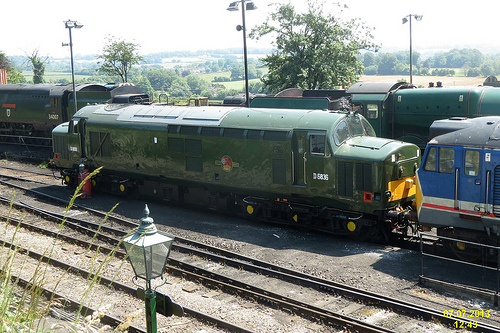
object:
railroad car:
[49, 98, 409, 236]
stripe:
[383, 174, 416, 203]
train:
[413, 95, 500, 259]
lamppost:
[139, 285, 164, 333]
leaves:
[319, 59, 336, 63]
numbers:
[319, 173, 323, 181]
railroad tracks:
[7, 261, 188, 332]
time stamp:
[434, 305, 499, 332]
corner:
[431, 289, 499, 331]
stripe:
[421, 196, 498, 226]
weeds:
[68, 219, 125, 328]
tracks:
[242, 255, 500, 326]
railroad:
[20, 100, 499, 332]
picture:
[2, 1, 495, 332]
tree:
[90, 43, 141, 83]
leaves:
[108, 46, 112, 48]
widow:
[436, 146, 455, 174]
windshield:
[343, 114, 365, 137]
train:
[3, 79, 165, 163]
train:
[370, 83, 499, 137]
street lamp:
[120, 203, 179, 293]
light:
[74, 20, 85, 30]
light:
[225, 0, 241, 13]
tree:
[254, 5, 360, 87]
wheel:
[439, 226, 487, 263]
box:
[70, 167, 93, 199]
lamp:
[61, 16, 78, 30]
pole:
[67, 29, 87, 117]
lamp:
[241, 0, 261, 12]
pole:
[240, 2, 257, 107]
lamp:
[400, 16, 410, 27]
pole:
[405, 22, 418, 82]